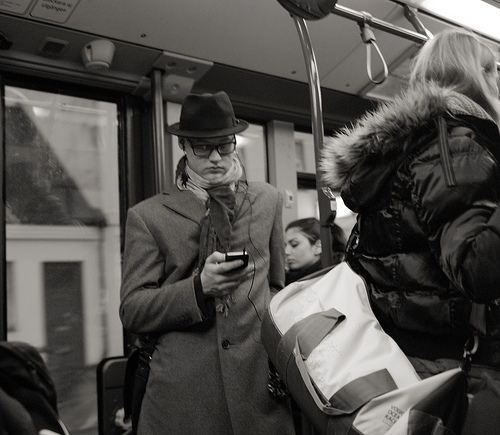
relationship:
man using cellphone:
[126, 86, 272, 241] [220, 248, 253, 260]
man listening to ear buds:
[126, 86, 272, 241] [179, 138, 187, 149]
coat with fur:
[377, 153, 494, 317] [361, 91, 451, 140]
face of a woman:
[288, 237, 299, 266] [287, 213, 320, 263]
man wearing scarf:
[126, 86, 272, 241] [202, 183, 236, 252]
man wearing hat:
[126, 86, 272, 241] [163, 91, 250, 137]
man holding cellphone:
[126, 86, 272, 241] [220, 248, 253, 260]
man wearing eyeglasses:
[126, 86, 272, 241] [194, 142, 237, 156]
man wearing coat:
[126, 86, 272, 241] [136, 190, 263, 426]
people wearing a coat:
[314, 28, 499, 435] [377, 153, 494, 317]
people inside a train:
[162, 38, 494, 289] [5, 2, 497, 426]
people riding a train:
[162, 38, 494, 289] [5, 2, 497, 426]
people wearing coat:
[314, 28, 499, 435] [377, 153, 494, 317]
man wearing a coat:
[126, 86, 272, 241] [136, 190, 263, 426]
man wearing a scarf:
[126, 86, 272, 241] [202, 183, 236, 252]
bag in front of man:
[270, 268, 435, 433] [126, 86, 272, 241]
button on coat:
[222, 337, 231, 349] [136, 190, 263, 426]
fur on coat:
[361, 91, 451, 140] [377, 153, 494, 317]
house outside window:
[1, 89, 111, 372] [7, 91, 122, 234]